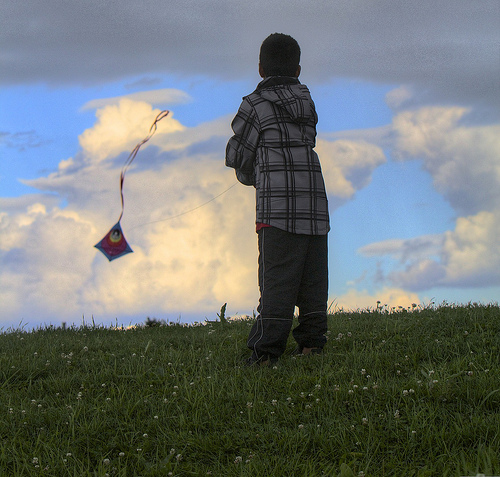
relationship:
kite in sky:
[90, 212, 140, 262] [0, 1, 497, 333]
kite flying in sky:
[92, 110, 169, 262] [0, 1, 497, 333]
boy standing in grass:
[224, 20, 346, 377] [186, 317, 262, 417]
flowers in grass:
[0, 325, 497, 476] [2, 302, 499, 475]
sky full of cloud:
[0, 1, 497, 333] [73, 90, 185, 161]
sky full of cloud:
[0, 1, 497, 333] [312, 136, 385, 203]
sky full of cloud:
[0, 1, 497, 333] [359, 95, 499, 288]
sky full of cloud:
[0, 1, 497, 333] [326, 285, 423, 314]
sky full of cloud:
[0, 1, 497, 333] [0, 154, 263, 329]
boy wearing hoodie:
[225, 32, 330, 369] [234, 75, 329, 231]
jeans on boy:
[246, 222, 328, 355] [224, 30, 331, 365]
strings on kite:
[101, 94, 186, 214] [82, 117, 181, 267]